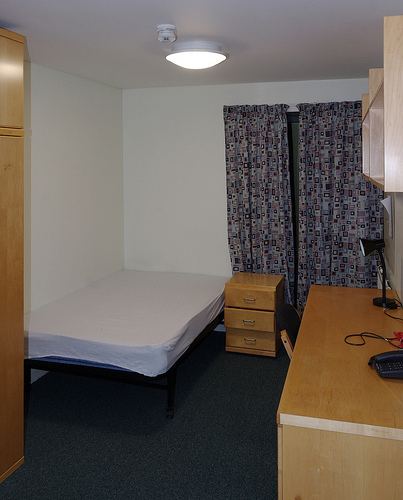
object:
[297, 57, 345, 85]
ceiling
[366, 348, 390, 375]
phone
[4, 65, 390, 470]
room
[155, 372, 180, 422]
leg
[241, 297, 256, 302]
handle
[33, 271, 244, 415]
bed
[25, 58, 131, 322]
wall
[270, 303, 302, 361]
chair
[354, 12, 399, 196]
wall shelf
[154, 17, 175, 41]
smoke alarm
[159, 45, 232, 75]
ceiling light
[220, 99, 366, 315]
curtain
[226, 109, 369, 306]
window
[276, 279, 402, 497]
desk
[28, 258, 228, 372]
sheet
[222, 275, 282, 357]
cabinet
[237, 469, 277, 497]
carpet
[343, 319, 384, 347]
cord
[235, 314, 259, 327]
handle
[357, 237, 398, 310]
lamp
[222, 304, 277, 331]
drawers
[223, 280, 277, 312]
drawers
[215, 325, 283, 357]
drawers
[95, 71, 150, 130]
corner